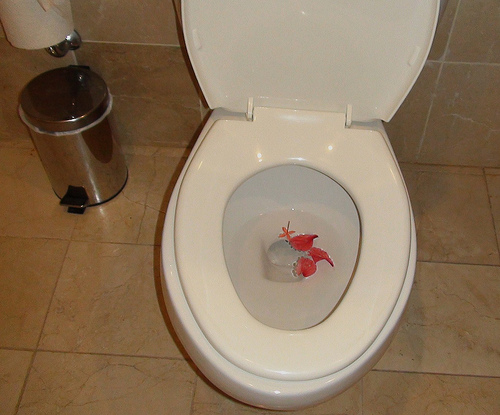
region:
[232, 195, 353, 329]
water of toilet is clean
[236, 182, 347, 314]
petals of flowers inside a toilet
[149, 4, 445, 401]
toilet is open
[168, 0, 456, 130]
lid of toilet is up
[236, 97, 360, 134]
hinge of toilet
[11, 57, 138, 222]
trash can next a toilet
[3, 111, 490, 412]
floor of bathroom is tiled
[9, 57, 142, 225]
trash can is color silver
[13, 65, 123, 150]
trash can has a white bag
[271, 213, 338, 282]
petals of flowers are pink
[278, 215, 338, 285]
flower petals in toilet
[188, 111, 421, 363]
bottom of toilet bowl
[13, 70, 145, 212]
silver foot-pedal trash can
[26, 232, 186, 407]
square-tile floor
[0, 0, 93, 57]
toilet paper holder with a roll of paper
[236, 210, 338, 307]
clean water in toilet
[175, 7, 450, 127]
toilet lid, half-seen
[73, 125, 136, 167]
reflection of toilet in trash can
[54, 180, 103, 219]
foot pedal for small trash can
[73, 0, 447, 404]
entire toilet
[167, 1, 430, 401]
A white toilet with an open lid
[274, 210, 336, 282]
Pink flower petals in a toilet bowl.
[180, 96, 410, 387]
An oval-shaped toilet seat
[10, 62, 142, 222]
A small metal garbage can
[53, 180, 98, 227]
A foot petal used to open a garbage can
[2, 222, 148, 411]
A tile floor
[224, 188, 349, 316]
Water in a toilet bowl.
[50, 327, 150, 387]
Grout in between tiles on the floor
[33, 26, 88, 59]
A silver metal object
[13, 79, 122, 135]
A garbage bag in a can.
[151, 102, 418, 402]
a white porcelain toilet bowl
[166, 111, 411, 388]
a white plastic toilet seat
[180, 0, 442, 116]
a white plastic toilet seat lid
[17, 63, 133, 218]
a chrome trash can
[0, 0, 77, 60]
a roll of toilet paper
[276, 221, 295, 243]
a small red leaf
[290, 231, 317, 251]
a small red leaf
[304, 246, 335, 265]
a small red leaf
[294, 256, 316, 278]
a small red leaf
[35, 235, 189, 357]
a brown floor tile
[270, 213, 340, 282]
Flower petals inside the toilet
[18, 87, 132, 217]
Metal trash can in the corner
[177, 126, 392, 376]
Toilet seat on the toilet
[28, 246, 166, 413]
Large tiles on the floor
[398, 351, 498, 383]
Line of grout between tile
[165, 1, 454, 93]
The toilet lid is raised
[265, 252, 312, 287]
Opening at the bottom of toilet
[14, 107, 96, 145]
Trash bag inside the can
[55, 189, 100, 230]
Pedal on front of trash can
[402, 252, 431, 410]
Shadow on the floor